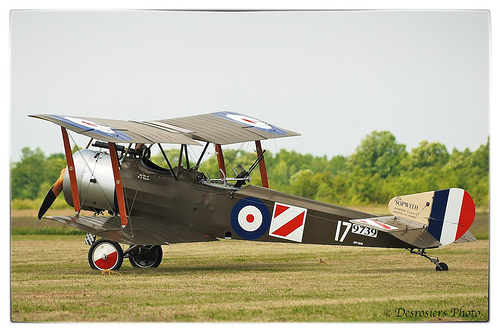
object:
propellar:
[36, 167, 68, 220]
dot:
[245, 214, 254, 223]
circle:
[229, 197, 271, 240]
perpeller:
[37, 168, 66, 221]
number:
[334, 219, 352, 243]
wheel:
[88, 238, 124, 271]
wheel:
[435, 262, 448, 272]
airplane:
[27, 110, 477, 272]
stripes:
[437, 188, 466, 248]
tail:
[348, 187, 477, 249]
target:
[229, 196, 271, 240]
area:
[6, 9, 494, 323]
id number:
[353, 224, 377, 237]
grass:
[7, 225, 486, 322]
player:
[246, 213, 255, 223]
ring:
[238, 205, 263, 232]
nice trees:
[343, 129, 409, 183]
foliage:
[325, 185, 349, 202]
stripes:
[386, 187, 476, 248]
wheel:
[127, 245, 163, 269]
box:
[260, 192, 308, 244]